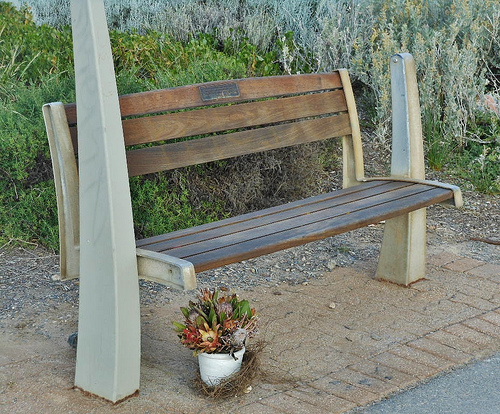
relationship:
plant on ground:
[180, 287, 256, 388] [3, 197, 493, 412]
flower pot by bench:
[199, 352, 245, 382] [42, 0, 464, 405]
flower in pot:
[180, 288, 254, 352] [172, 336, 359, 384]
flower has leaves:
[180, 288, 254, 352] [174, 290, 291, 378]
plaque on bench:
[194, 73, 241, 102] [131, 61, 430, 265]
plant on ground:
[180, 287, 256, 388] [266, 271, 486, 411]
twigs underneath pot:
[212, 387, 279, 412] [151, 333, 236, 385]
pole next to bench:
[53, 0, 163, 413] [38, 63, 465, 345]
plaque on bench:
[197, 79, 239, 101] [42, 0, 464, 405]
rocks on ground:
[255, 223, 417, 309] [0, 96, 493, 411]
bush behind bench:
[2, 8, 314, 261] [40, 47, 465, 361]